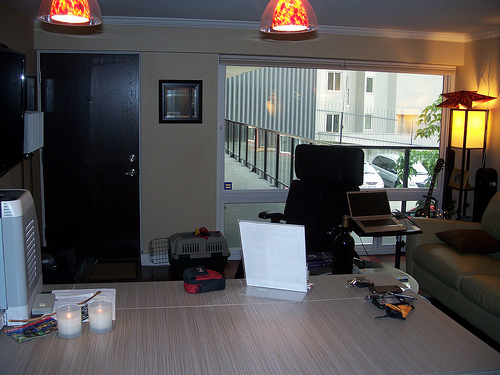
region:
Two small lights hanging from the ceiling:
[28, 0, 326, 52]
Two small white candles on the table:
[51, 295, 124, 346]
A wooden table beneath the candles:
[127, 308, 342, 368]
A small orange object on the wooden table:
[378, 302, 424, 326]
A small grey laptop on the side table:
[345, 188, 411, 235]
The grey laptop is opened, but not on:
[347, 190, 412, 236]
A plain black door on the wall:
[45, 62, 142, 259]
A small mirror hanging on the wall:
[157, 79, 204, 121]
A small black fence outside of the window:
[232, 123, 329, 185]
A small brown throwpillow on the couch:
[438, 219, 498, 261]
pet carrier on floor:
[148, 225, 231, 266]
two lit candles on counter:
[52, 299, 114, 341]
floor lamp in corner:
[447, 108, 493, 215]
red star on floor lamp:
[441, 85, 494, 217]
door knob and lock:
[123, 154, 138, 179]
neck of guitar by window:
[413, 153, 448, 215]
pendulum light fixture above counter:
[254, 0, 323, 42]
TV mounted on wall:
[1, 45, 28, 177]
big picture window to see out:
[216, 61, 456, 261]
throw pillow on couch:
[437, 229, 497, 254]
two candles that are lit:
[44, 286, 123, 351]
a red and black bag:
[173, 257, 228, 302]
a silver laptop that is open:
[330, 162, 400, 245]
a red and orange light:
[246, 1, 326, 41]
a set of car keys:
[339, 266, 377, 295]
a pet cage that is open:
[134, 206, 234, 268]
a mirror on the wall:
[149, 65, 213, 139]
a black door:
[32, 47, 142, 265]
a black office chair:
[257, 120, 362, 251]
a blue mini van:
[364, 145, 401, 184]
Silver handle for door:
[121, 150, 139, 184]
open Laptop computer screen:
[341, 188, 396, 218]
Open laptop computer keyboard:
[351, 213, 405, 233]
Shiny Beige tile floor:
[159, 323, 261, 366]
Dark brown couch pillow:
[436, 224, 495, 255]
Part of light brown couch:
[444, 257, 493, 312]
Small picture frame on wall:
[154, 74, 206, 134]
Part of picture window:
[224, 72, 456, 147]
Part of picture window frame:
[211, 57, 226, 222]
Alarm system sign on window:
[219, 180, 234, 194]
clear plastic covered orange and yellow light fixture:
[256, 0, 322, 42]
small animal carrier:
[147, 222, 233, 279]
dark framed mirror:
[157, 76, 205, 126]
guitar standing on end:
[414, 156, 450, 218]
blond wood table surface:
[3, 271, 498, 373]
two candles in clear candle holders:
[55, 296, 114, 341]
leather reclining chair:
[256, 142, 367, 276]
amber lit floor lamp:
[443, 108, 488, 219]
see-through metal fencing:
[225, 118, 440, 211]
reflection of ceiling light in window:
[262, 88, 282, 123]